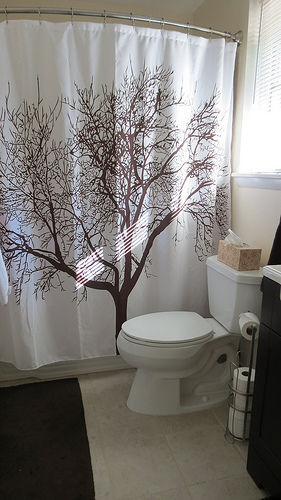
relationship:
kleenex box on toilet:
[216, 230, 263, 273] [115, 256, 265, 417]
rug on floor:
[0, 376, 97, 499] [2, 367, 260, 500]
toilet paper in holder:
[232, 367, 255, 395] [224, 358, 255, 446]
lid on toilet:
[120, 310, 213, 344] [115, 256, 265, 417]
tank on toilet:
[206, 254, 266, 334] [115, 256, 265, 417]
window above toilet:
[233, 2, 280, 187] [115, 256, 265, 417]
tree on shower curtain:
[3, 56, 232, 356] [1, 19, 241, 373]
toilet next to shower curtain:
[115, 256, 265, 417] [1, 19, 241, 373]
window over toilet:
[233, 2, 280, 187] [115, 256, 265, 417]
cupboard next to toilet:
[246, 277, 280, 500] [115, 256, 265, 417]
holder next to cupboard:
[224, 358, 255, 446] [246, 277, 280, 500]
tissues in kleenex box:
[221, 228, 244, 248] [216, 230, 263, 273]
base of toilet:
[113, 310, 240, 421] [115, 256, 265, 417]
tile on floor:
[107, 448, 187, 499] [2, 367, 260, 500]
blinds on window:
[253, 0, 281, 168] [233, 2, 280, 187]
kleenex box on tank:
[216, 230, 263, 273] [206, 254, 266, 334]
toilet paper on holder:
[239, 312, 260, 340] [224, 358, 255, 446]